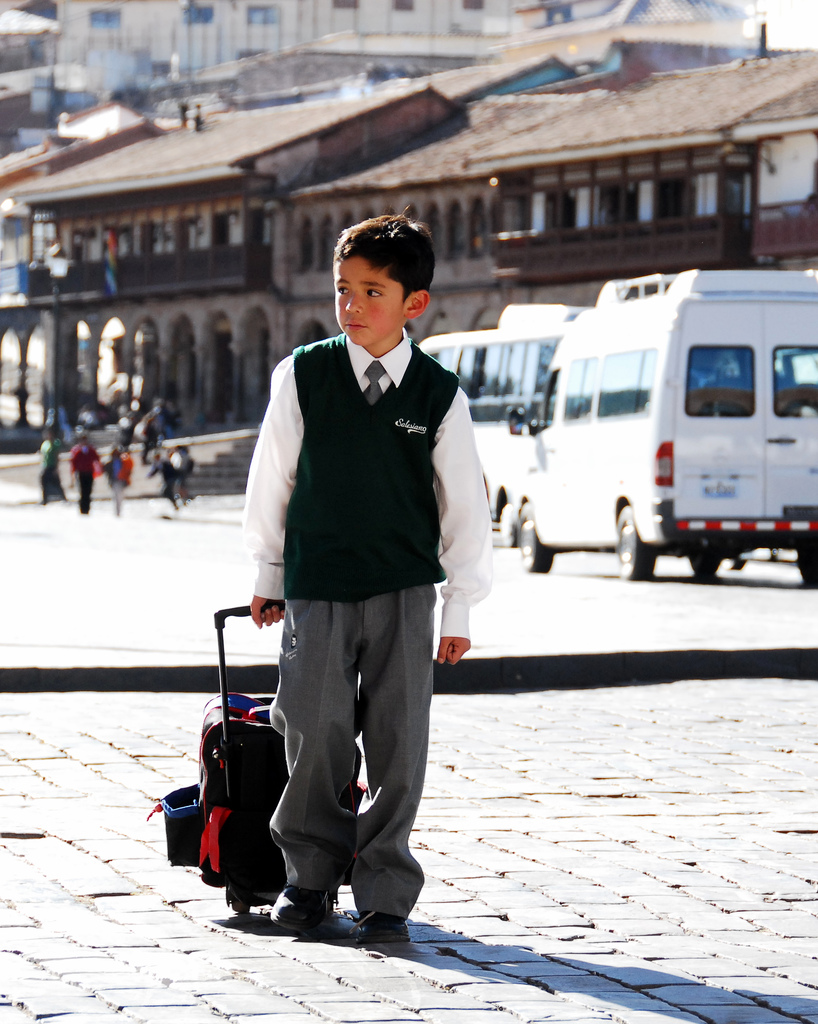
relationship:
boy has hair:
[242, 214, 494, 941] [334, 208, 438, 292]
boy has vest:
[242, 214, 494, 941] [286, 333, 460, 602]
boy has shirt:
[242, 214, 494, 941] [246, 325, 494, 631]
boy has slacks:
[242, 214, 494, 941] [272, 592, 437, 922]